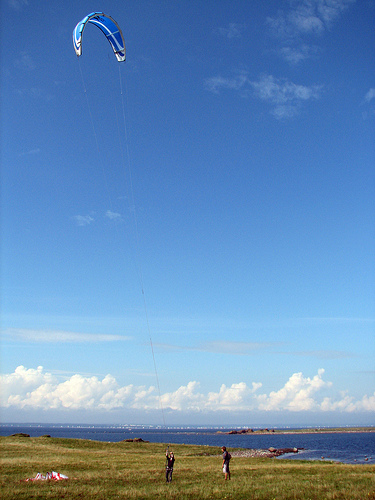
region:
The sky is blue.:
[50, 224, 323, 363]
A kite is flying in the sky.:
[60, 8, 231, 159]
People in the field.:
[143, 448, 281, 490]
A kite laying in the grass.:
[30, 457, 92, 480]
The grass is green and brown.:
[74, 439, 135, 489]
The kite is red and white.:
[21, 464, 81, 485]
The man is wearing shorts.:
[212, 442, 247, 488]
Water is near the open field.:
[118, 420, 255, 452]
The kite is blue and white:
[68, 15, 152, 85]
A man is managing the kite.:
[148, 439, 178, 486]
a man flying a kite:
[149, 437, 196, 480]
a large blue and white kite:
[61, 7, 136, 67]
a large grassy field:
[3, 433, 337, 495]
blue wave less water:
[231, 429, 366, 464]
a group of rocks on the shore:
[242, 442, 305, 457]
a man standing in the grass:
[212, 441, 247, 482]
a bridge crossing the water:
[12, 420, 199, 430]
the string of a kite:
[134, 315, 166, 422]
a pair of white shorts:
[220, 462, 232, 475]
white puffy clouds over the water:
[22, 369, 320, 414]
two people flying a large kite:
[50, 10, 275, 485]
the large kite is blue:
[49, 10, 157, 73]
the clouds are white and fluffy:
[2, 353, 368, 417]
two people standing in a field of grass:
[150, 441, 252, 489]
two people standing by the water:
[140, 414, 268, 490]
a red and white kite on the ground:
[18, 465, 80, 491]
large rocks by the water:
[118, 435, 151, 446]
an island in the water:
[226, 422, 374, 440]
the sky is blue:
[145, 17, 367, 227]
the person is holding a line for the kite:
[64, 66, 183, 454]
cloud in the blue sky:
[210, 60, 324, 155]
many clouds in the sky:
[34, 349, 337, 420]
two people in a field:
[143, 436, 241, 498]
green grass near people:
[95, 442, 141, 488]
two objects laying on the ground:
[24, 456, 77, 492]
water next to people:
[320, 432, 355, 455]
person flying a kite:
[151, 438, 189, 493]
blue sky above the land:
[147, 285, 210, 354]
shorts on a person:
[217, 464, 236, 477]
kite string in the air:
[117, 326, 184, 450]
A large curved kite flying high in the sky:
[57, 5, 139, 61]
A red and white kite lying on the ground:
[28, 465, 83, 485]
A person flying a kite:
[159, 440, 183, 487]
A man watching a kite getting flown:
[215, 435, 241, 484]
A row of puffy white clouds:
[23, 363, 321, 413]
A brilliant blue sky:
[94, 204, 266, 273]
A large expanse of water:
[87, 426, 329, 461]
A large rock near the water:
[268, 443, 283, 450]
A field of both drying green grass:
[73, 444, 142, 485]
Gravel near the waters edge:
[221, 445, 269, 460]